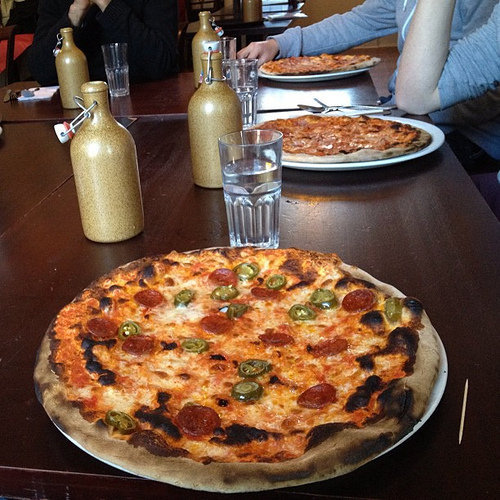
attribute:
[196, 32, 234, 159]
jar bottle — small, olive green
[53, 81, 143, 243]
bottle — gold, glass, metallic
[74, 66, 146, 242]
bottle — brown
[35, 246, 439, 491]
pizza — round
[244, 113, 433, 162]
pizza — whole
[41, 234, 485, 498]
pasta — red, black, green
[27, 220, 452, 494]
pizza — round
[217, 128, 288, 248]
glass — filled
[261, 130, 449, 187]
plate — white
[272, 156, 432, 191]
plate — white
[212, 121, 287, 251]
glass — clear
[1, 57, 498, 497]
table — brown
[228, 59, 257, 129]
glass — clear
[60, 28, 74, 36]
brim — narrow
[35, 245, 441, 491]
pie — whole, pizza